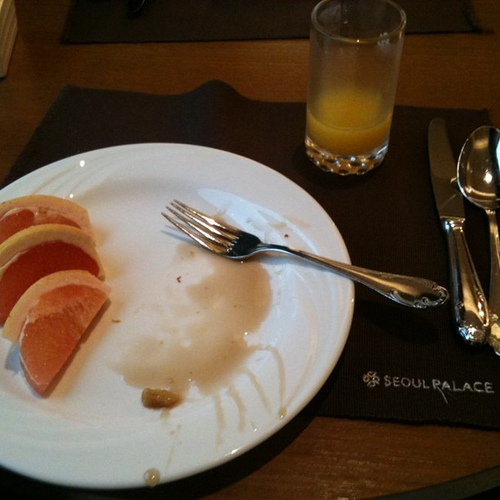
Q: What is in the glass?
A: Orange Juice.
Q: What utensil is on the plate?
A: Fork.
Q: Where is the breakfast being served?
A: Seoul Palace.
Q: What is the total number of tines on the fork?
A: 4.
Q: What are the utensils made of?
A: Metal.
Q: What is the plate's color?
A: White.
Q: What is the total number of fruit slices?
A: 3.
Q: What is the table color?
A: Brown.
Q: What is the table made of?
A: Wood.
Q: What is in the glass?
A: Orange juice.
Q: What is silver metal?
A: The utensils.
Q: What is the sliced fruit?
A: Grapefruit.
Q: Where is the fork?
A: Top of plate.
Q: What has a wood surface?
A: Table.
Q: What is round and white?
A: Plate.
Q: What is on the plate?
A: Food.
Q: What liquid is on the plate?
A: Syrup.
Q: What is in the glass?
A: Orange juice.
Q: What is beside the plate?
A: Silverware.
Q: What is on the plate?
A: A fork.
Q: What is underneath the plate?
A: Place mat.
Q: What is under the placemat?
A: Table.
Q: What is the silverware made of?
A: Silver.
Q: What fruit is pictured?
A: A grapefruit.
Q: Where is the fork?
A: On the plate.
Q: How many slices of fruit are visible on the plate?
A: Three.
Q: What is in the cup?
A: Orange juice.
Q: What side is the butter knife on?
A: The left.